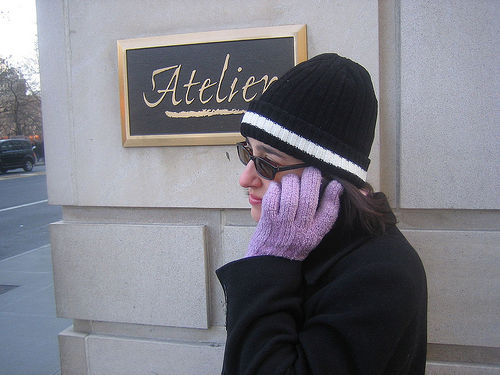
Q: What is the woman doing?
A: Talking on the phone.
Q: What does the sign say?
A: Atelier.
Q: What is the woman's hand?
A: A purple glove.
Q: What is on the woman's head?
A: A hat.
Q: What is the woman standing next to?
A: A building.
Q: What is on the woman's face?
A: Sunglasses.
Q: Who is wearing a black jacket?
A: A woman.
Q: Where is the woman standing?
A: On a corner.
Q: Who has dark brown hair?
A: The person.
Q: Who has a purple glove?
A: The person.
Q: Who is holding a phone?
A: The woman.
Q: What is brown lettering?
A: The sign.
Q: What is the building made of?
A: Bricks.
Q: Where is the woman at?
A: On the corner of the building.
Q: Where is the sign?
A: Next to the woman.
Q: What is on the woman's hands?
A: Blue gloves.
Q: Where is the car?
A: To the left of the building.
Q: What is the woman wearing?
A: Gloves.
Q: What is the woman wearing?
A: Hat.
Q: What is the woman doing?
A: Talking.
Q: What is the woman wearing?
A: Jacket.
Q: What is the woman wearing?
A: Hat.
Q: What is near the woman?
A: Wall.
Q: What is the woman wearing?
A: Phone.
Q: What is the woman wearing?
A: Glasses.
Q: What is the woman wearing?
A: Gloves.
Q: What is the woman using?
A: Phone.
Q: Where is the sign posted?
A: Wall.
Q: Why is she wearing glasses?
A: Sunny.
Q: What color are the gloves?
A: Purple.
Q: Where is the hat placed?
A: Head.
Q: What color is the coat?
A: Black.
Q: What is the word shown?
A: Atelier.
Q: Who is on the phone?
A: Woman.